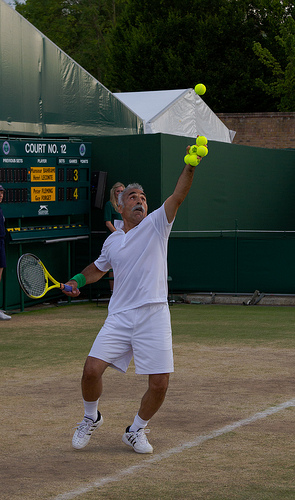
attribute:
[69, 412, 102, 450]
shoe — white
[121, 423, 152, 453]
shoe — white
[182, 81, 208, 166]
balls — neon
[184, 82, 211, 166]
balls — green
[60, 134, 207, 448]
player — white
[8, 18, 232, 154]
tents — white, silver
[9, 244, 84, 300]
racket — yellow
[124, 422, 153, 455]
shoe — white, tennis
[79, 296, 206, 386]
shorts — white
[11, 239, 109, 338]
racket — yellow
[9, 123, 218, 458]
player — tennis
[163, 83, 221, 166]
tennis balls — for tennis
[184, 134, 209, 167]
tennis balls — yellow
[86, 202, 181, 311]
t-shirt — white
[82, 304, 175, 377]
shorts — white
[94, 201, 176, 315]
shirt — white